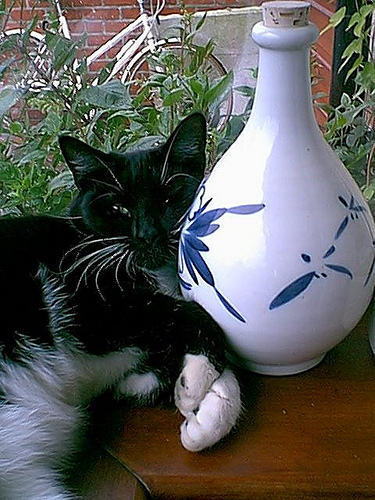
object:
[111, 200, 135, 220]
eye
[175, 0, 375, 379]
flower vase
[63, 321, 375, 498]
brown table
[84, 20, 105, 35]
brick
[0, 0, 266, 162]
wall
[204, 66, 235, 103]
leaves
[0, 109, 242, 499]
cat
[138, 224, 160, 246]
nose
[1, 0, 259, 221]
plants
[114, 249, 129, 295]
whiskers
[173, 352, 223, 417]
claw